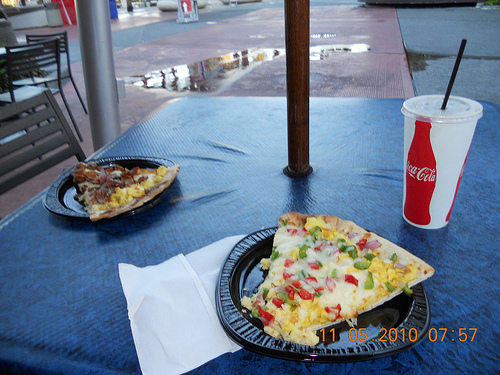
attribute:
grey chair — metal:
[1, 38, 88, 143]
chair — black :
[46, 25, 86, 105]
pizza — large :
[265, 210, 432, 325]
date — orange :
[318, 326, 425, 348]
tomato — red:
[260, 301, 282, 332]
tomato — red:
[324, 277, 334, 291]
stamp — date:
[312, 321, 480, 346]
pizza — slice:
[71, 155, 180, 220]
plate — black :
[214, 220, 434, 360]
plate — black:
[41, 152, 181, 219]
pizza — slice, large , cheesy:
[235, 210, 437, 350]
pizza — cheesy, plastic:
[65, 160, 182, 221]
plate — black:
[44, 157, 176, 219]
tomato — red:
[312, 241, 324, 258]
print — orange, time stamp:
[300, 311, 476, 353]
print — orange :
[378, 327, 420, 342]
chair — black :
[0, 89, 85, 209]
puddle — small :
[120, 40, 372, 93]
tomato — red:
[289, 271, 305, 298]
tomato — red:
[313, 277, 330, 296]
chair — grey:
[3, 75, 85, 203]